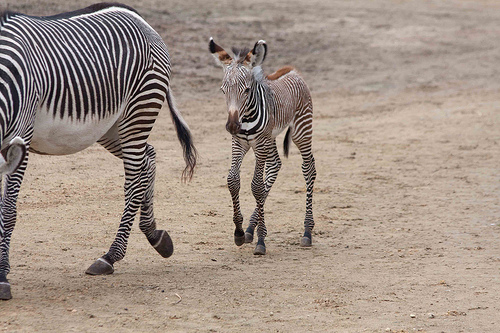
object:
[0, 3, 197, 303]
zebra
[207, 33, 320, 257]
baby zebra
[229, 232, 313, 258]
hooves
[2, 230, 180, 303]
hooves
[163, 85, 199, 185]
tail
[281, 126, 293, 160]
short tail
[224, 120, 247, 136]
black nose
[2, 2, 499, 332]
ground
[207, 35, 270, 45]
white tips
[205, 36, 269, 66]
ears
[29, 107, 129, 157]
belly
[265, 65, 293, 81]
brown fur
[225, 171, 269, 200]
knees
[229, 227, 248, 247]
front hoof up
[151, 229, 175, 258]
raised left hoof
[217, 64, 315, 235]
many stripes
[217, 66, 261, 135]
face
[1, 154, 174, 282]
legs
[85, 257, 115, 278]
hoof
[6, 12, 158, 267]
stripe pattern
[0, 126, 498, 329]
gravel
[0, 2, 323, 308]
zebras